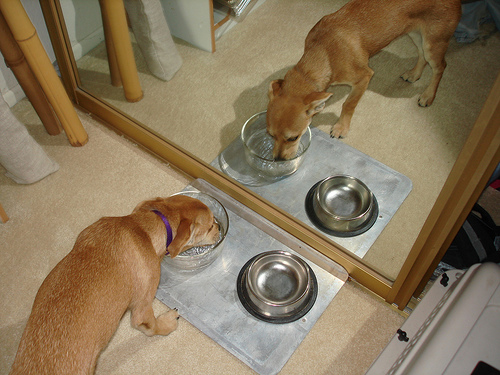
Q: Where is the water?
A: Glass bowl.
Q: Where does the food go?
A: Silver bowl.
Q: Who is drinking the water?
A: Dog.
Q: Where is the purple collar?
A: Dog's neck.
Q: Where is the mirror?
A: In front of dog.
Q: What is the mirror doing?
A: Reflecting.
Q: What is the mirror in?
A: Frame.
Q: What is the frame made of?
A: Wood.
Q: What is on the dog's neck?
A: Collar.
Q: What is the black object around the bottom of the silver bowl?
A: Vase.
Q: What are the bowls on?
A: Tray.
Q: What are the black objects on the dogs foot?
A: Nails.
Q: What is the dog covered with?
A: Fur.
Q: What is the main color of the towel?
A: Blue.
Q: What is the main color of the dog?
A: Brown.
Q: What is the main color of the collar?
A: Purple.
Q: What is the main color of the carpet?
A: Brown.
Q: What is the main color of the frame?
A: Brown.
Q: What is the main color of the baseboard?
A: White.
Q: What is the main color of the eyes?
A: Black.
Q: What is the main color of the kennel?
A: White.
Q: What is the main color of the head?
A: Brown.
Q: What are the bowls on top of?
A: Mat.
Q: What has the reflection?
A: Mirror.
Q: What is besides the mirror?
A: Carrier.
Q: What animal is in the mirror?
A: Dog.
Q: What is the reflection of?
A: Dog eating.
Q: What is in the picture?
A: Dog eating.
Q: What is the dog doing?
A: Drinking.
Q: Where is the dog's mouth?
A: Water bucket.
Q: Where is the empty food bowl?
A: On the right.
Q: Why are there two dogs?
A: Mirror.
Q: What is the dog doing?
A: Drinking.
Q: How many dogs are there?
A: One.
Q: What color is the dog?
A: Brown.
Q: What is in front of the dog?
A: A mirror.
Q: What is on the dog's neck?
A: A collar.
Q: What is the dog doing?
A: Drinking.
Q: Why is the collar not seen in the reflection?
A: The dog's fur hides it from that angle.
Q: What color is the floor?
A: Tan.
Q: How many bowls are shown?
A: Two.